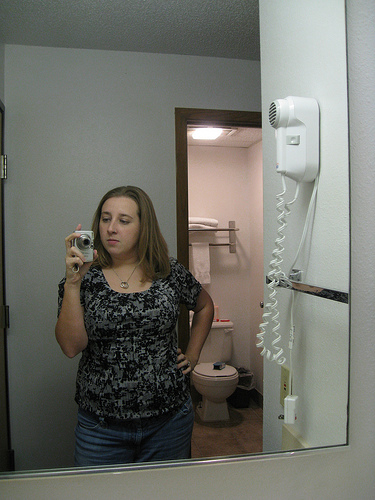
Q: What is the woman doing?
A: Taking picture.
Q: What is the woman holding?
A: Camera.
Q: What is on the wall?
A: Hair dryer.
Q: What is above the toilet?
A: Towels.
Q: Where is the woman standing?
A: Bathroom.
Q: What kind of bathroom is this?
A: Hotel.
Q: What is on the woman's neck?
A: Necklace.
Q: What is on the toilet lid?
A: Complimentary soap.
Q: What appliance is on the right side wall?
A: Hair Dryer.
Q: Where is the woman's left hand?
A: Hip.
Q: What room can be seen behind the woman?
A: Bathroom.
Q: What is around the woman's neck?
A: Necklace.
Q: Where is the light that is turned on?
A: Bathroom.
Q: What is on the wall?
A: A blow dryer.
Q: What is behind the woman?
A: A toilet.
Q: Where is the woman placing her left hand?
A: On her hip.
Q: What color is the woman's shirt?
A: Black and grey.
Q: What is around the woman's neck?
A: A necklace.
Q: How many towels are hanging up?
A: One.